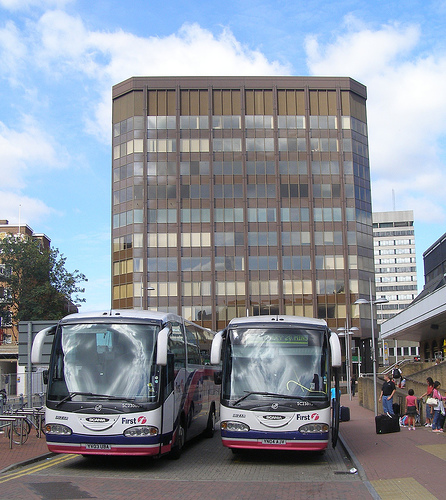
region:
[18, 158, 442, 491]
Both buses are taking passengers home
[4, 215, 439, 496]
Two buses are picking up people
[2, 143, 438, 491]
Two buses are operating in a city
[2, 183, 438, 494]
Two buses are carrying happy tourists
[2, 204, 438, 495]
The buses belong to the same company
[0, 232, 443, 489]
The buses both have the same owner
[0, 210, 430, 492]
The buses are operating in daytime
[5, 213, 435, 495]
The buses are designed for long trips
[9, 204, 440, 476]
The buses both have air conditioning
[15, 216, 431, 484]
The buses are taking on passengers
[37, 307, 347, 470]
two white buses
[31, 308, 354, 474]
two white buses with blue and red stripes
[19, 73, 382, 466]
brown building with windows behind two white buses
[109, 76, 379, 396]
brown building with windows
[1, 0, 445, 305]
sky is blue with puffy white clouds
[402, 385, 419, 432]
girl standing in red shirt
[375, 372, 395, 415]
man in blue jeans with black shirt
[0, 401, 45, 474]
bicycles parked on brick sidewalk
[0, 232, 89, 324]
green tree in the background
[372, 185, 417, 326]
white building behind brown building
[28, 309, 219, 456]
a blue pink and white large bus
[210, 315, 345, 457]
a blue pink and white large bus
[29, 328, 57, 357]
the long white mirror of a bus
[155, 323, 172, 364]
the long white mirror of a bus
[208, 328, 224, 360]
the long white mirror of a bus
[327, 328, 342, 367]
the long white mirror of a bus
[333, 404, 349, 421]
a big black suitcase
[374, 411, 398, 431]
a big black suitcase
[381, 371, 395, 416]
a person standing on the sidewalk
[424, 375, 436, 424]
a person standing on the sidewalk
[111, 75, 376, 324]
brown building behind the busses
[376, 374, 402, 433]
man with a black shirt and jeans standing on the sidewalk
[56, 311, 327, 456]
two white, purple, and pink busses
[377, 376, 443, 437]
group of people standing outside on a sidewalk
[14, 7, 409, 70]
clear blue sky with white clouds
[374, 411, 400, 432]
black suitcase sitting on the ground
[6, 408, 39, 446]
silver metal bike racks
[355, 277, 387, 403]
two streetlights on a pole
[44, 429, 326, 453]
purple and pink stripes on the fronts of the busses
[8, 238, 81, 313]
tree in front of a building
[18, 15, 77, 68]
white clouds in blue sky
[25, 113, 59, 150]
white clouds in blue sky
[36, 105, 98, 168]
white clouds in blue sky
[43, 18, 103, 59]
white clouds in blue sky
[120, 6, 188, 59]
white clouds in blue sky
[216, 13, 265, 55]
white clouds in blue sky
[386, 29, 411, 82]
white clouds in blue sky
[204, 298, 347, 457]
white passenger bus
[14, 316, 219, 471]
white bus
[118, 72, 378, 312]
large brown building